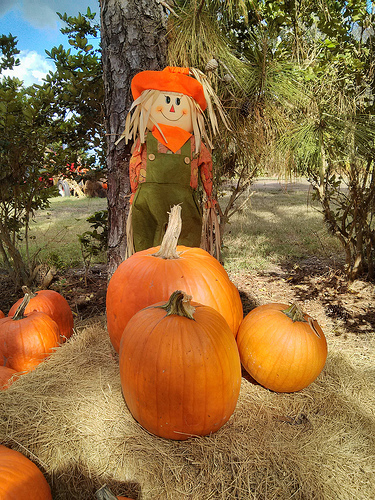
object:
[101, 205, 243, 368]
pumpkin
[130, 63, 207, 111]
hat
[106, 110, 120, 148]
bark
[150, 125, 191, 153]
scarf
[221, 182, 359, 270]
shadow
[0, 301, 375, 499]
grass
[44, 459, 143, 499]
shadow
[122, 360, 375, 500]
shadow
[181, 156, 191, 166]
button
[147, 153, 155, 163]
button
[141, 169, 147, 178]
button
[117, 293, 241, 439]
pumpkin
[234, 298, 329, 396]
pumpkin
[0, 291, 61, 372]
pumpkin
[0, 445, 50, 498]
pumpkin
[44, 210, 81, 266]
patch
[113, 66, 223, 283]
scarecrow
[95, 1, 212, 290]
tree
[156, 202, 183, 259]
stem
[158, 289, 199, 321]
stem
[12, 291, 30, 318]
stem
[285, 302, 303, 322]
stem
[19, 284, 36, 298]
stem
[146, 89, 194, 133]
face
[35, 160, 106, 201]
house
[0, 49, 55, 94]
cloud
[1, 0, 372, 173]
sky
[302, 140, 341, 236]
branch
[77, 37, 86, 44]
branch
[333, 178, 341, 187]
leaves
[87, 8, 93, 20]
leaves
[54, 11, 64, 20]
leaves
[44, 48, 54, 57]
leaves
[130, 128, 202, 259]
overall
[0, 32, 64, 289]
bush